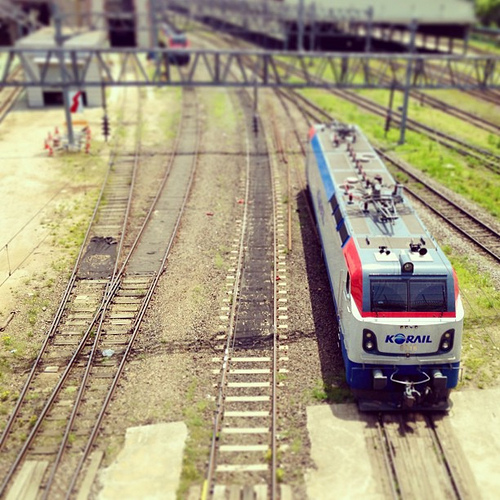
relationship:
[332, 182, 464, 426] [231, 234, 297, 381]
train on railroad tracks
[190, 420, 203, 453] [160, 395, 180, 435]
grass on ground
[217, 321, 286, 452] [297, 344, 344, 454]
railroad tracks on ground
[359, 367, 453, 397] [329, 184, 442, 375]
bumper on train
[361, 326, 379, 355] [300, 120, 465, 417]
lights on train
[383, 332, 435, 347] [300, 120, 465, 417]
brand name on train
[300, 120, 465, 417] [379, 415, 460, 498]
train on rail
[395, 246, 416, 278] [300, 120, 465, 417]
light on train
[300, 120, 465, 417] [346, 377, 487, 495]
train on tracos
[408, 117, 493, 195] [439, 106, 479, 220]
weeds on tracks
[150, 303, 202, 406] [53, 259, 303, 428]
gravel between tracks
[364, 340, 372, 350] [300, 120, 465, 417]
lights on train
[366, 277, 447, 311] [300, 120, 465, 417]
winshield front train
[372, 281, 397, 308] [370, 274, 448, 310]
reflection on windshield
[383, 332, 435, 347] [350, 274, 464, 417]
brand name front train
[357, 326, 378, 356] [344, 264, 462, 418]
headlight front train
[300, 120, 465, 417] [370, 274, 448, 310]
train has windshield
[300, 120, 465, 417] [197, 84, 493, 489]
train on tracks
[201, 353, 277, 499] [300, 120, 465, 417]
railroad tracks next train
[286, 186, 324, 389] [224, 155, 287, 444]
gravel side tracks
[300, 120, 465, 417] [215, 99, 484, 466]
train on tracks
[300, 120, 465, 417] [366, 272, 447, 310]
train has window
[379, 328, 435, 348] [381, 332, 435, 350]
brand name on train company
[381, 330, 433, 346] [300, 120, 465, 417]
headlights on train